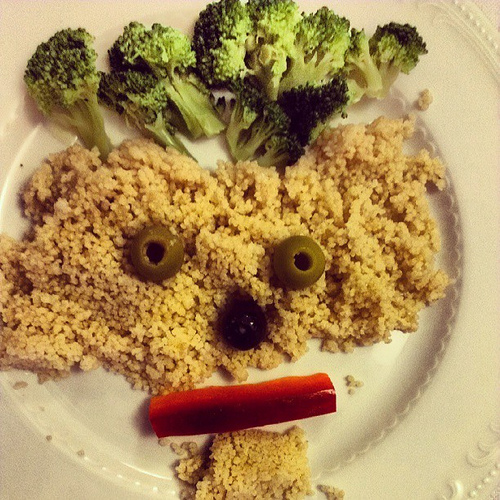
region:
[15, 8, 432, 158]
The pieces of broccoli on the plate.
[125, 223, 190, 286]
The olive on the left.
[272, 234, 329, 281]
The olive on the right.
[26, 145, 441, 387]
The mound of couscous rice on the plate.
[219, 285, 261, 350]
The black olive in the center of the two green olives.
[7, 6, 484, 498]
The white plate the food is on.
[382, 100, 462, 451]
The ribbon design in the center of the plate.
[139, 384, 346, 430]
The red food item on the plate.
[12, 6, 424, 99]
The top tree-shaped part of the broccoli pieces.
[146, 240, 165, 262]
The center of the olive on the left.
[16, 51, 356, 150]
The broccoli is green.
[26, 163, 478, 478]
The plate is round.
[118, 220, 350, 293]
Two olives make up the face.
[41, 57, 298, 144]
The broccoli is cooked.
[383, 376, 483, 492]
The plate has ridges.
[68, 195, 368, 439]
The food looks like a face.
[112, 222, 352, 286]
The olives are green.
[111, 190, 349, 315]
The olives have holes in the middle.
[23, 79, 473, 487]
The plate is hallow in the middle.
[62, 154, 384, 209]
Brown rice.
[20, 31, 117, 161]
cooked green broccoli on white plate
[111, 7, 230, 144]
cooked green broccoli on white plate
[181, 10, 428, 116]
cooked green broccoli on white plate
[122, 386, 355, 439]
cooked orange carrot on white plate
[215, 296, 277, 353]
black olive on white plate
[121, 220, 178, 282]
green olive on white plate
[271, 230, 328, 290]
green olive on white plate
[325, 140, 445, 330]
brown rice on white plate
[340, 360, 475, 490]
white plate covered with food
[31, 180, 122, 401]
brown rice on white plate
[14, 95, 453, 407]
A face made from food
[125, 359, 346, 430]
A red pepper mouth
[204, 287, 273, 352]
A black olive nose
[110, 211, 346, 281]
Two green olive eyes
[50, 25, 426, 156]
Green broccoli hair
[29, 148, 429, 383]
Grain forming the base of a face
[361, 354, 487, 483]
A decorative white plate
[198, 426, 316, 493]
A tongue comprised of grain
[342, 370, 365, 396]
Loose grain not with the rest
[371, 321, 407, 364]
Light reflecting off the plate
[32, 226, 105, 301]
couscous is so yummy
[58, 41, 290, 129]
broccoli as hair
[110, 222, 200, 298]
green olive as an eye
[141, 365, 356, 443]
red pepper slice as a mouth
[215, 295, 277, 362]
black olive as a nose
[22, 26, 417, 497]
smiley face dinner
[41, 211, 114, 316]
yummy grain cooked with seasoning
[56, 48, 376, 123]
green vegetable that resembles a tree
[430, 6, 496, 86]
nice white plate design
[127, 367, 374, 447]
looks like a vegetable mouth